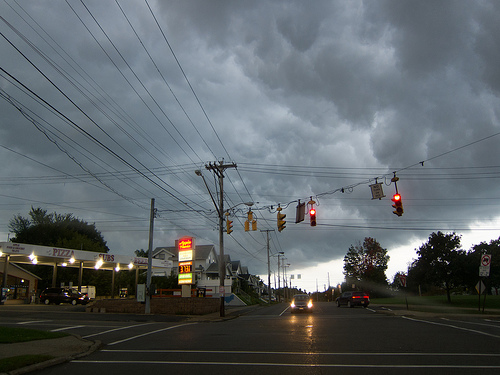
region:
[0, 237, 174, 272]
A canopy over a gas station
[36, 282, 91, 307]
A minivan getting gas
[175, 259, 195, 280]
A sign displaying the price for gas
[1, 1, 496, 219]
Dark storm clouds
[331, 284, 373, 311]
A car turning right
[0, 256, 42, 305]
Convenience store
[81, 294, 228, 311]
A low brick wall at a street corner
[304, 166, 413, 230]
The stoplight is red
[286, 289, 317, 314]
A car with headlights on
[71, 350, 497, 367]
Crosswalk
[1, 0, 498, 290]
The sky is dark and stormy.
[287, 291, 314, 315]
The car is stopped at a red light.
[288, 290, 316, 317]
The car has its headlights on.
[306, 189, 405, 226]
The stop lights are red.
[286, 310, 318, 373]
The headlights on the car are reflecting off of the wet street.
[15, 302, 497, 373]
White lines are painted on the ground.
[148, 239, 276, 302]
Houses line the right side of the street.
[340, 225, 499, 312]
Big trees grow in the park across the street from the houses.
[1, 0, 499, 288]
Many electrical wires are above the street.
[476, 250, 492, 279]
A no through truck sign is on the right side of the intersection.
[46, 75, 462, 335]
stormy clouds over a commercial street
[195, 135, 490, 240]
traffic lights hanging from wires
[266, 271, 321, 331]
headlights of car approaching intersection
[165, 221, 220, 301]
lighted sign showing time and advertisements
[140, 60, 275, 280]
utility pole supporting several wires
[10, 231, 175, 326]
elevated words describing food available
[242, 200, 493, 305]
lighter sky behind dark clouds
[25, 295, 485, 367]
white lines bordering the intersection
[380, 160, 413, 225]
hanging traffic light showing glowing red light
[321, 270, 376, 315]
red tail lights of car moving down the street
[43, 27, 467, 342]
An overcast scene at dusk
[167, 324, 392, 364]
A patch of wet road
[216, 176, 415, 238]
Several overhead traffic lights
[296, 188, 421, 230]
Two traffic lights that are red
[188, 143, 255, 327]
A utility pole with many wires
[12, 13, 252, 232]
A large number of overhead electrical wires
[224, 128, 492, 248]
A wire suspending several traffic lights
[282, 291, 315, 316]
A car with headlines on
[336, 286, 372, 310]
A car with rear lights on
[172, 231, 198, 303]
Sign advertising several businesses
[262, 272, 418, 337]
There are 2 cars in the road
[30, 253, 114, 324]
One car is at the gas station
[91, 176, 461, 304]
The sky is cloudy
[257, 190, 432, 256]
The lights are red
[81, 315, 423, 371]
The street is black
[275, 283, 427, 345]
The cars lights are on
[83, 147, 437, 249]
The wires send electricity throughout the city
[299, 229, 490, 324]
There are trees on the side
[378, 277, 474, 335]
The grass is green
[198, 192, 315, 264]
The light cases are yellow